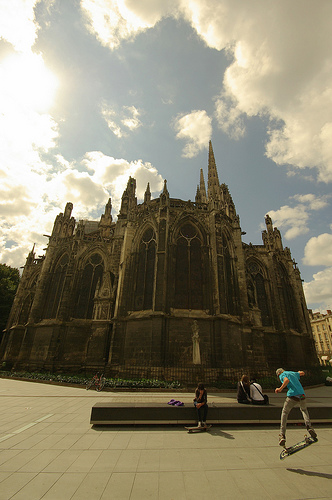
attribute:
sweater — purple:
[167, 393, 182, 410]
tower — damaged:
[14, 200, 79, 373]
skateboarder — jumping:
[271, 364, 321, 446]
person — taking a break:
[189, 375, 214, 436]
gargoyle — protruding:
[40, 233, 52, 250]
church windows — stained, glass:
[169, 220, 208, 309]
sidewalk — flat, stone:
[0, 378, 330, 498]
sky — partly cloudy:
[1, 1, 329, 308]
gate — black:
[0, 356, 327, 388]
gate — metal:
[0, 368, 328, 390]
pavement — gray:
[0, 377, 328, 498]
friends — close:
[236, 375, 267, 402]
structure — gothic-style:
[2, 139, 322, 385]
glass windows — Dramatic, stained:
[124, 214, 241, 320]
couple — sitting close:
[235, 374, 270, 404]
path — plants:
[1, 365, 156, 389]